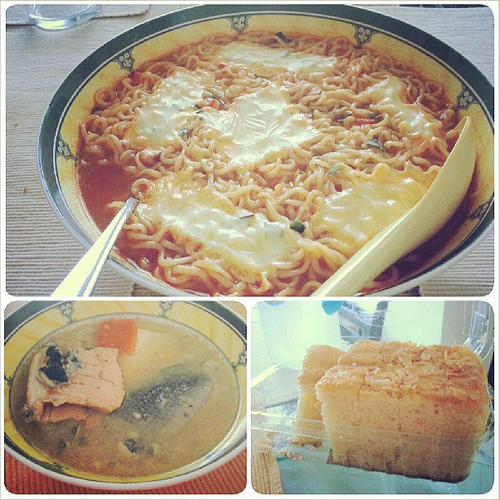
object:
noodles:
[174, 123, 338, 231]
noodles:
[143, 247, 195, 285]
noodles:
[127, 155, 164, 173]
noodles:
[275, 250, 313, 282]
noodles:
[370, 145, 411, 162]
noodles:
[306, 169, 326, 191]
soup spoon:
[308, 114, 480, 300]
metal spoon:
[47, 195, 140, 298]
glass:
[27, 4, 100, 33]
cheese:
[205, 84, 322, 164]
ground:
[321, 130, 368, 207]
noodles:
[98, 90, 145, 157]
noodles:
[270, 167, 310, 209]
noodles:
[311, 84, 380, 128]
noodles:
[127, 223, 213, 280]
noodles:
[302, 39, 341, 58]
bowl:
[38, 5, 496, 298]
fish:
[107, 362, 214, 458]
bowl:
[3, 301, 247, 494]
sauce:
[76, 160, 150, 221]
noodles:
[270, 179, 320, 219]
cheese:
[125, 70, 319, 277]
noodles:
[254, 54, 438, 205]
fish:
[18, 342, 127, 424]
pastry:
[291, 341, 489, 482]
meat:
[20, 339, 125, 426]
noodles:
[83, 33, 458, 297]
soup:
[77, 34, 464, 297]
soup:
[113, 97, 325, 245]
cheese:
[125, 70, 319, 170]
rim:
[37, 34, 127, 238]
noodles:
[152, 72, 377, 259]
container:
[250, 355, 493, 496]